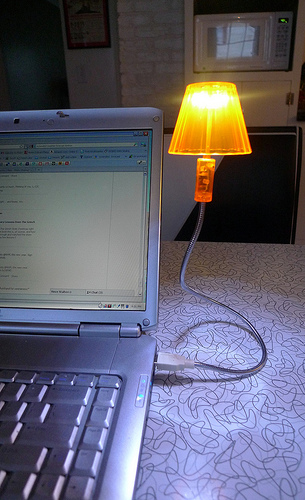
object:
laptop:
[1, 105, 165, 498]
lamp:
[156, 81, 266, 378]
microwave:
[194, 12, 297, 74]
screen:
[1, 129, 154, 310]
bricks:
[117, 1, 186, 128]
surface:
[131, 239, 304, 499]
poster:
[62, 0, 111, 49]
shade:
[167, 81, 251, 156]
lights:
[137, 375, 149, 409]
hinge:
[77, 322, 122, 340]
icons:
[0, 131, 153, 310]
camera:
[14, 118, 21, 125]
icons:
[96, 302, 131, 311]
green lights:
[279, 18, 289, 24]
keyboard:
[1, 368, 124, 499]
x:
[142, 129, 150, 137]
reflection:
[193, 14, 272, 67]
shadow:
[172, 317, 259, 351]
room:
[0, 0, 304, 500]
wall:
[0, 1, 185, 129]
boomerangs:
[133, 241, 305, 500]